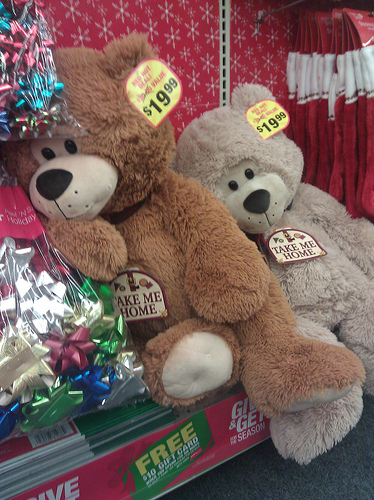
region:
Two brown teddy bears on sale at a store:
[12, 34, 373, 411]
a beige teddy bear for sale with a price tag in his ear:
[173, 95, 372, 469]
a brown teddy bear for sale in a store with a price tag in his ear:
[10, 42, 351, 456]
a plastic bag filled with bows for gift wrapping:
[1, 213, 160, 441]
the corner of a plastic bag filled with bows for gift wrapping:
[0, 3, 89, 144]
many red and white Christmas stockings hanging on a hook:
[274, 11, 372, 215]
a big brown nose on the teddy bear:
[34, 168, 74, 201]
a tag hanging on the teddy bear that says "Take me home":
[268, 225, 330, 266]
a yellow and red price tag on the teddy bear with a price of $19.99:
[122, 60, 193, 127]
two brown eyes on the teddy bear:
[223, 168, 263, 190]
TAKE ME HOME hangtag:
[273, 242, 314, 256]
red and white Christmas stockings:
[304, 55, 369, 177]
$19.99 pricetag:
[135, 72, 176, 106]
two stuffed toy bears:
[122, 135, 272, 321]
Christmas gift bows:
[4, 8, 44, 128]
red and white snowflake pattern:
[168, 2, 215, 60]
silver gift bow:
[12, 275, 62, 332]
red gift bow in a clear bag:
[56, 336, 80, 365]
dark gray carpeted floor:
[214, 467, 358, 495]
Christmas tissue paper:
[72, 421, 148, 434]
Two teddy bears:
[2, 45, 372, 461]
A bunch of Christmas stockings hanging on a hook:
[289, 7, 373, 207]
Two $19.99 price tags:
[105, 53, 296, 140]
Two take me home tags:
[103, 225, 335, 320]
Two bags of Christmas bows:
[0, 2, 146, 408]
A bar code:
[26, 417, 82, 447]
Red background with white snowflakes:
[156, 3, 273, 81]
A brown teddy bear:
[15, 67, 306, 476]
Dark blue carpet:
[260, 450, 373, 496]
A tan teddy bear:
[174, 99, 373, 461]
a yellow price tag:
[122, 56, 188, 130]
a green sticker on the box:
[111, 407, 216, 498]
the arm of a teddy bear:
[155, 187, 272, 327]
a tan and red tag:
[111, 267, 167, 323]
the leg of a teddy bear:
[234, 290, 371, 419]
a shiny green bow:
[14, 377, 86, 434]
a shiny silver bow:
[95, 352, 151, 413]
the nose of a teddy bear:
[28, 162, 77, 199]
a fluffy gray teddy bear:
[171, 80, 372, 465]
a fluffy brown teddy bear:
[4, 28, 366, 422]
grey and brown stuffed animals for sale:
[26, 24, 358, 410]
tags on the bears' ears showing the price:
[112, 45, 320, 162]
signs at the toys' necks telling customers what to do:
[96, 209, 343, 323]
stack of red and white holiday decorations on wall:
[275, 1, 364, 218]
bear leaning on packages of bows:
[0, 122, 133, 450]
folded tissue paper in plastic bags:
[1, 380, 176, 493]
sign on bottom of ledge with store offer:
[35, 381, 286, 494]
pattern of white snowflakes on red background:
[153, 0, 276, 82]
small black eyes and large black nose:
[210, 153, 287, 234]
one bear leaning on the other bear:
[22, 36, 354, 320]